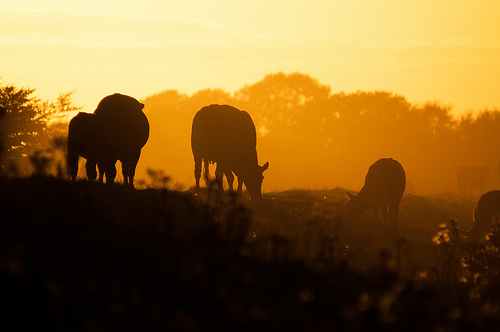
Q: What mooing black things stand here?
A: Cows.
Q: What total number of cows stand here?
A: Five.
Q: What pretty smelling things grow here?
A: Flowers.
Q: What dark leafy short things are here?
A: Bushes.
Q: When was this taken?
A: Sunset.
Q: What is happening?
A: Cattle grazing.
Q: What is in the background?
A: Trees.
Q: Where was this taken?
A: A pasture.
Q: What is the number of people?
A: Zero.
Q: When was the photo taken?
A: At sunset or sunrise in a pasture.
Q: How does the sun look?
A: Orange.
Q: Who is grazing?
A: The cow.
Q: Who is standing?
A: The cows.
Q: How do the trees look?
A: Leafy.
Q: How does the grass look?
A: Tall.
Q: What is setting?
A: The sun.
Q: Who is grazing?
A: Five cows.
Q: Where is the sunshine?
A: Low on the horizon.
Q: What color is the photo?
A: Yellow.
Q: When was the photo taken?
A: Evening.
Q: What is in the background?
A: Trees.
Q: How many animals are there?
A: Five.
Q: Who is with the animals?
A: No one.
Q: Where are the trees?
A: In the back.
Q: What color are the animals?
A: Black.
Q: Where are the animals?
A: Pasture.